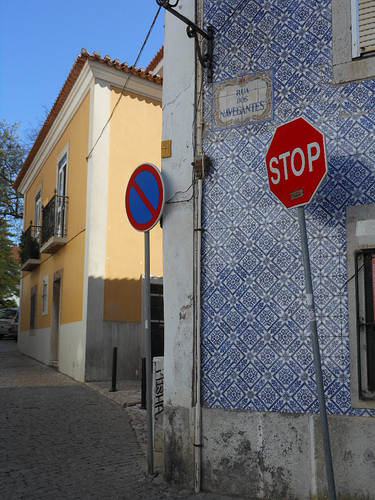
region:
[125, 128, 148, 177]
the wall is yellow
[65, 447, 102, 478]
the street is gray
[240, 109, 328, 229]
the sign is red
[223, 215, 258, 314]
the wall is blue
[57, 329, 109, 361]
the wall is white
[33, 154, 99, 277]
the window has terrace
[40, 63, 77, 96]
the gutter is orange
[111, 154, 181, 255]
the sign is blue and white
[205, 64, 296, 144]
the sign says RUA DOS NAVEGANTES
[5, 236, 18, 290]
the leaves are green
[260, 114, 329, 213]
stop sign is on pole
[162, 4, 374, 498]
stop sign in front of building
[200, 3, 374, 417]
wall on building is colorful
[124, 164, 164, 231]
do not enter sign is next to stop sign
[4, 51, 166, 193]
building has clay tile roof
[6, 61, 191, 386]
building in back is yellow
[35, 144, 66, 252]
balcony on building in back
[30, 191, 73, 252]
balcony is in front of window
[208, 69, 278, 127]
wall has street sign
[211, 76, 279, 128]
sign is in french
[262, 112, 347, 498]
red stop sign on a tall metal pole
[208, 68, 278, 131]
street sign painted onto tiles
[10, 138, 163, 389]
yellow and white painted house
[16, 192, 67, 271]
balconies outside first floor windows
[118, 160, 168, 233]
sign with a red outlined circle with a blue fill and a red diagonal line through it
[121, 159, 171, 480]
no waiting sign on a tall metal pole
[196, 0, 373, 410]
decorative blue and white tiles on an outside wall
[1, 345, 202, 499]
street covered with cobble stones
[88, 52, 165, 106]
roof tiles casting a shadow on a wall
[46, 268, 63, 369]
doorway in a yellow and white building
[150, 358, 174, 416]
Writing on a wall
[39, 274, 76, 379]
A doorway of a building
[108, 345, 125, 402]
Posts in a ally way entrance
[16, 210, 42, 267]
A balcony of a building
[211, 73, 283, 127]
The name of the building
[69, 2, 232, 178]
A power line connecting two buildings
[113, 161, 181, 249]
A do not enter sign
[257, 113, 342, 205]
A stop sign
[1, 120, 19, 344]
A tall green tree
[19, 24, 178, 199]
The roof of a building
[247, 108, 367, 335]
A stop sign.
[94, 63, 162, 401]
An alley.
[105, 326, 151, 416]
Two black metal poles in front of the alley.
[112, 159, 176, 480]
A street sign.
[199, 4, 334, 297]
The wall has tiles, arranged in a geometric pattern, on it.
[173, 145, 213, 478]
Electrical wiring.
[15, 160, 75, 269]
The building has two small balconies.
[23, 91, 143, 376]
The building is white and yellow.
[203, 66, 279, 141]
The name of the street.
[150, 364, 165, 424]
Graffiti.